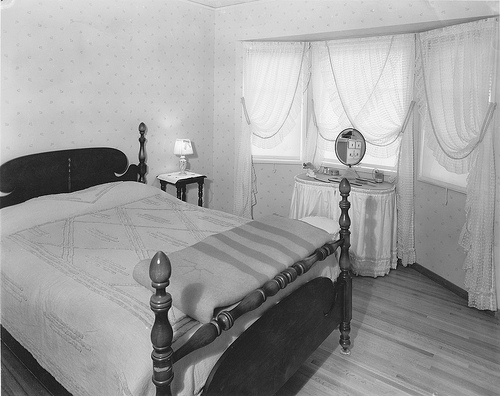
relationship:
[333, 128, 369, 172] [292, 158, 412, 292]
mirror on table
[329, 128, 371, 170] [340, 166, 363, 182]
mirror sitting on fixture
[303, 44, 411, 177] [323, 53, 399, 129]
window letting in light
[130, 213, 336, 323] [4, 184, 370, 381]
blanket sitting on bed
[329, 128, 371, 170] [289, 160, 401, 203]
mirror on table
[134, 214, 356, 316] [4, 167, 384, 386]
blanket at foot of bed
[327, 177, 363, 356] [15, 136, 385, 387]
post on bed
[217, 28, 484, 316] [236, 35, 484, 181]
curtains on windows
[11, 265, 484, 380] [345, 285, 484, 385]
floors made of wood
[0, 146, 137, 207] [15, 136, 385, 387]
bed head on bed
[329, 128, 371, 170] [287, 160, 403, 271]
mirror on table